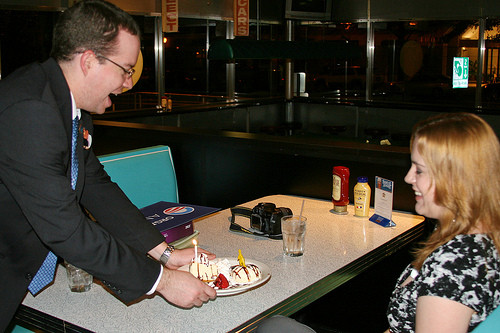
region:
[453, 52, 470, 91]
A green and white sign.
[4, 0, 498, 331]
A celebration.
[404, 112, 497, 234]
The woman is smiling.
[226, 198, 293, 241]
A camera sitting on the table.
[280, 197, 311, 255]
Drink with a straw sitting on the table.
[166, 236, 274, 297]
A plate of goodies with a lit candle.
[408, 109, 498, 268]
A woman with strawberry blonde hair.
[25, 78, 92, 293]
A blue and white polka dot tie.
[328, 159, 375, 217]
The condiment bottles, ketchup and mustard are sitting on the table.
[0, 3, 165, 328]
A man in a black suit.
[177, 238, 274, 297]
birthday cake and ice cream on a plate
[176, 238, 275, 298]
desert on a plate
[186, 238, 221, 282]
cake with a candle in it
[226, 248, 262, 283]
scoop of ice cream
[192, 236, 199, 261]
white lit candle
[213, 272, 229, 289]
strawberry on a plate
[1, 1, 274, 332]
man placing a dessert on a table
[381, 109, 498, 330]
smiling woman sitting down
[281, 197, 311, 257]
glass of water on a table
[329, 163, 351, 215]
bottle of ketchup on a table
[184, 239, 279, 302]
birthday dessert surprise with candles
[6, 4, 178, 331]
man in grey suit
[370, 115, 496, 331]
woman in black and white top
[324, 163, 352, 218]
bottle of ketchup on table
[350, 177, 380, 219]
bottle of mustard on table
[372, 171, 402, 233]
plastic menu card on table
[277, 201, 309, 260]
glass of water with plastic straw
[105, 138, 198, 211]
baby blue vinyl seat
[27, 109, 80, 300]
medium blue men's tie with small design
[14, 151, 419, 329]
speckled formica table top